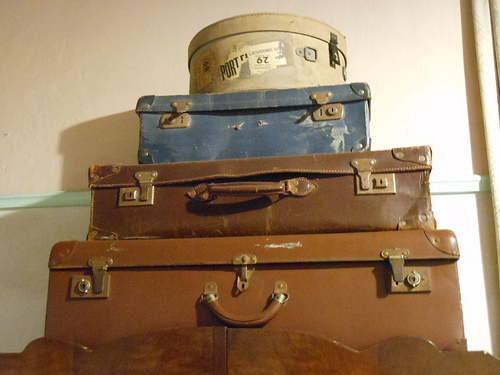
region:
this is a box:
[48, 240, 439, 344]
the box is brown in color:
[301, 263, 362, 323]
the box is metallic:
[303, 280, 363, 326]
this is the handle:
[208, 284, 287, 329]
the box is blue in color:
[221, 115, 290, 143]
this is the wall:
[35, 13, 139, 110]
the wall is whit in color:
[23, 8, 90, 107]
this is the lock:
[347, 170, 397, 198]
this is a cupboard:
[261, 333, 373, 374]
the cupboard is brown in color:
[264, 326, 334, 361]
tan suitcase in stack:
[47, 243, 464, 343]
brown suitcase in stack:
[97, 165, 427, 226]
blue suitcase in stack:
[128, 89, 372, 162]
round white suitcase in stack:
[184, 22, 341, 92]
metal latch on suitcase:
[380, 252, 417, 294]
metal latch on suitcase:
[70, 256, 122, 299]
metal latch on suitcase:
[124, 172, 154, 207]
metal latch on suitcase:
[350, 158, 393, 192]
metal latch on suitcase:
[167, 97, 186, 122]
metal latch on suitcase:
[317, 92, 339, 119]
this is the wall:
[48, 16, 103, 67]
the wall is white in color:
[58, 12, 108, 53]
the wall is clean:
[50, 15, 125, 84]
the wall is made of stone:
[14, 213, 44, 255]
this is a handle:
[202, 289, 289, 325]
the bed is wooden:
[38, 333, 453, 374]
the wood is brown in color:
[238, 337, 282, 372]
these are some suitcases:
[45, 93, 452, 323]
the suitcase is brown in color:
[306, 276, 343, 311]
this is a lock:
[381, 248, 428, 293]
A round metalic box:
[180, 24, 356, 91]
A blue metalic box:
[140, 91, 377, 160]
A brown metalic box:
[83, 159, 433, 229]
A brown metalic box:
[49, 239, 474, 341]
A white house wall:
[13, 61, 82, 168]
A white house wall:
[1, 4, 154, 71]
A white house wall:
[0, 216, 36, 338]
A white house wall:
[462, 205, 497, 337]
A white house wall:
[388, 84, 486, 129]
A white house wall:
[351, 9, 466, 69]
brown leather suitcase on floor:
[43, 238, 467, 346]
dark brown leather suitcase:
[81, 145, 436, 235]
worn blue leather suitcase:
[132, 82, 373, 159]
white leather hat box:
[184, 10, 349, 90]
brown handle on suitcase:
[203, 289, 284, 326]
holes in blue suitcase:
[230, 117, 267, 133]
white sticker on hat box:
[223, 39, 288, 81]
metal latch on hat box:
[329, 32, 339, 67]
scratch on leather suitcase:
[262, 240, 302, 250]